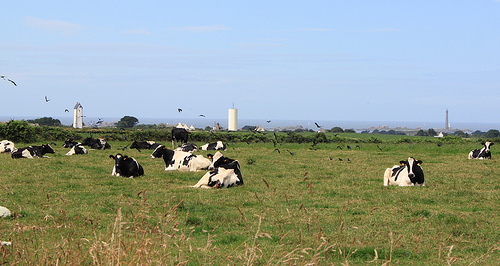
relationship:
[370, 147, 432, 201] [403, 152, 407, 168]
cow has ear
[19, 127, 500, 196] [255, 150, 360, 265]
cattle rest in grass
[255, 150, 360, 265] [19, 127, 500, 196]
grass under cattle